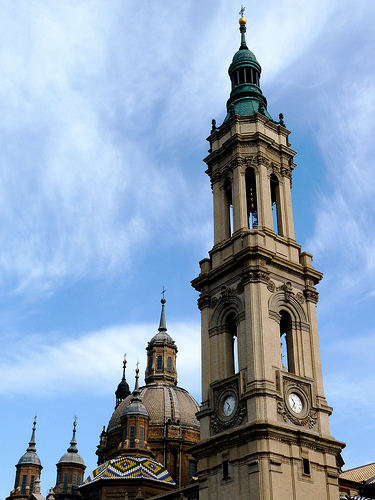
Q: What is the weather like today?
A: It is partly cloudy.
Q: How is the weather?
A: It is partly cloudy.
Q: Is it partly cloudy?
A: Yes, it is partly cloudy.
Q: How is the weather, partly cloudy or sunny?
A: It is partly cloudy.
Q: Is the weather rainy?
A: No, it is partly cloudy.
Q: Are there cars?
A: No, there are no cars.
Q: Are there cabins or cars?
A: No, there are no cars or cabins.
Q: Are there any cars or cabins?
A: No, there are no cars or cabins.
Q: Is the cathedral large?
A: Yes, the cathedral is large.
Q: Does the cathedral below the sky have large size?
A: Yes, the cathedral is large.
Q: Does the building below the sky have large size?
A: Yes, the cathedral is large.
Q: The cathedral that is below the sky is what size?
A: The cathedral is large.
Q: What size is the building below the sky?
A: The cathedral is large.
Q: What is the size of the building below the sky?
A: The cathedral is large.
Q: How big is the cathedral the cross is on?
A: The cathedral is large.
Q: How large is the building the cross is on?
A: The cathedral is large.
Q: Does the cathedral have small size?
A: No, the cathedral is large.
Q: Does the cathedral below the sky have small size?
A: No, the cathedral is large.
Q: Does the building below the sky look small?
A: No, the cathedral is large.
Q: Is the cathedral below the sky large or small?
A: The cathedral is large.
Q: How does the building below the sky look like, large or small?
A: The cathedral is large.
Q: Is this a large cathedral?
A: Yes, this is a large cathedral.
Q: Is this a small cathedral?
A: No, this is a large cathedral.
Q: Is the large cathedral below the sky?
A: Yes, the cathedral is below the sky.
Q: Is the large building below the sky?
A: Yes, the cathedral is below the sky.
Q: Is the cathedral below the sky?
A: Yes, the cathedral is below the sky.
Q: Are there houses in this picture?
A: No, there are no houses.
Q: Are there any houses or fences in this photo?
A: No, there are no houses or fences.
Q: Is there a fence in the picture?
A: No, there are no fences.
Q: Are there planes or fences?
A: No, there are no fences or planes.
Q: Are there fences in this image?
A: No, there are no fences.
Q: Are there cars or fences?
A: No, there are no fences or cars.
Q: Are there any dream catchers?
A: No, there are no dream catchers.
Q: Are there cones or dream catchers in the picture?
A: No, there are no dream catchers or cones.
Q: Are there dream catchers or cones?
A: No, there are no dream catchers or cones.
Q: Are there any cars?
A: No, there are no cars.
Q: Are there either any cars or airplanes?
A: No, there are no cars or airplanes.